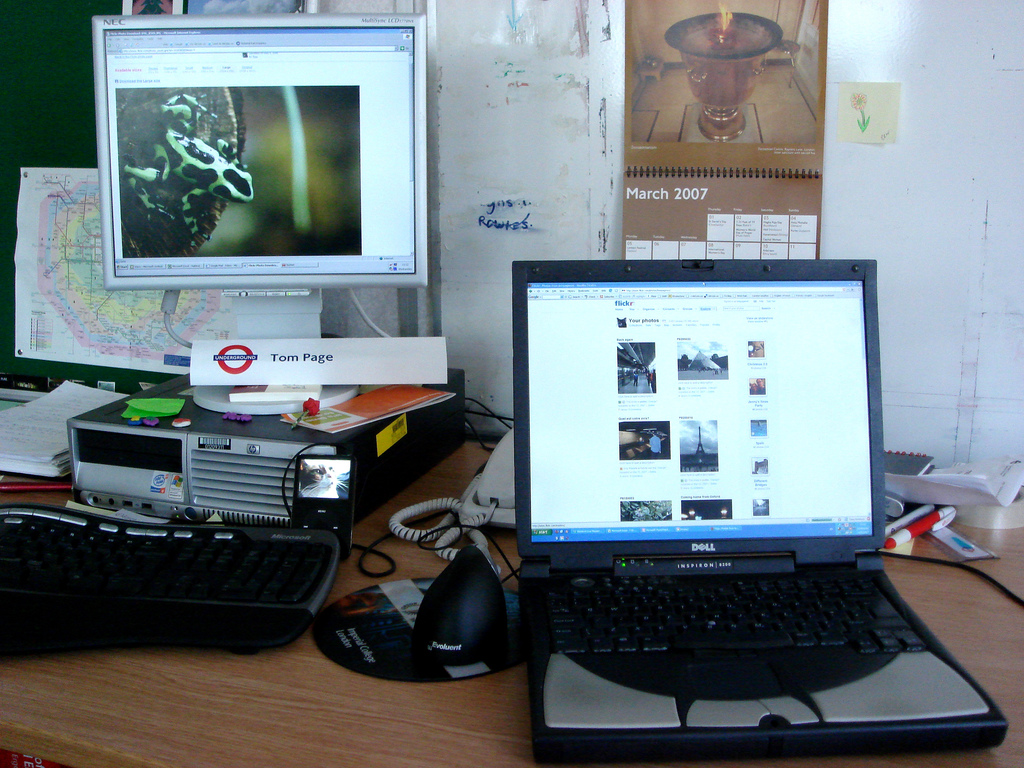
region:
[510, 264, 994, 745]
a laptop on a desk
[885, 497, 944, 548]
pens on the desk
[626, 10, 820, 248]
a calendar on the wall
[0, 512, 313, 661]
a black keyboard on the desk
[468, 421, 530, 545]
a white phone on the desk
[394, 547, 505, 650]
a black computer mouse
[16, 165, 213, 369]
a paper hanging on the wall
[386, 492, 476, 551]
the white phone cord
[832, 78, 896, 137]
a post it note on the wall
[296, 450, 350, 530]
an ipod on the desk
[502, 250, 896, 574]
monitor of a laptop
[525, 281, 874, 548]
screen of a black laptop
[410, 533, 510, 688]
black mouse on a desk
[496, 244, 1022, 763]
black laptop on a desk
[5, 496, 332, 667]
black keyboard on a desk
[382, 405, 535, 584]
white phone on a desk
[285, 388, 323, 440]
red flower on a computer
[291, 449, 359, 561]
cell phone on a desk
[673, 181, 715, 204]
year on a calendar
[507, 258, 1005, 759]
Black laptop is open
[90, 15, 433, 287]
Silver monitor on top of computer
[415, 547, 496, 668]
Black computer mouse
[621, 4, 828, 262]
Calendar hung on the wall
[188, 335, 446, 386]
Desk name tag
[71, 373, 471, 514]
Computer sitting under the monitor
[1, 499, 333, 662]
Specialized Keyboard is black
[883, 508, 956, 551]
Red and white ink pen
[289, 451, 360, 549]
Black ipod playing music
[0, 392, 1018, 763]
Desk is covered with odds and ends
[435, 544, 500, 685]
Black computer mouse on mouse pad.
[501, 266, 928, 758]
Black laptop sitting on top of desk.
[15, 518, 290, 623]
Black buttons on keyboard.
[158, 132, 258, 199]
Picture of a frog on computer monitor.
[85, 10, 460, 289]
Computer monitor is silver.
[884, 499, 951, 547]
Red and white pen sitting on desk.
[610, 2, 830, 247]
Calender on back wall.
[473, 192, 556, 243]
Blue writing on back wall.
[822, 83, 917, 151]
Picture of a flower on back wall.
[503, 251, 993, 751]
open black laptop on the desk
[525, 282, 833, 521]
screen on the laptop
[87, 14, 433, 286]
desktop computer monitor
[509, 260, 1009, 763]
a black laptop on the table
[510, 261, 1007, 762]
a black Dell laptop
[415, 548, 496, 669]
a black computer mouse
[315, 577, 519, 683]
a dark circular mouse pad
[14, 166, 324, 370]
a colorful map behind the monitor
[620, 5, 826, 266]
a calender behind the laptop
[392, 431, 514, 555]
part of a hand held phone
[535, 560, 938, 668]
Black keys on laptop computer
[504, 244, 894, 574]
A laptop screen turned on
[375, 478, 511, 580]
A white telephone chord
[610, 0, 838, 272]
Calendar hanging on the wall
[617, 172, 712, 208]
"March 2007" written on calendar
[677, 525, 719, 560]
"DELL" written on a laptop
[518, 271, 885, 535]
a laptop screen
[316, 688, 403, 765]
a desk that is brown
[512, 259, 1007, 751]
Laptop sitting open on a desk.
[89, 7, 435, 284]
Computer monitor displays a frog.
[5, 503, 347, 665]
Curved black and silver keyboard.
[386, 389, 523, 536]
White corded landline phone.